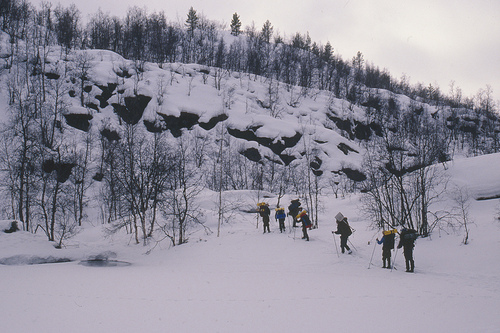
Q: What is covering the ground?
A: Snow.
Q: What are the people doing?
A: Skiing.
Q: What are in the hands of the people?
A: Ski poles.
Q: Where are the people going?
A: Uphill.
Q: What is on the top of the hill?
A: Trees.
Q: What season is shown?
A: Winter.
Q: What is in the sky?
A: Clouds.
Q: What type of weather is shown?
A: Cloudy and cold.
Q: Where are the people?
A: Hiking in the mountains.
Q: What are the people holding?
A: Hiking poles.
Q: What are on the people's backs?
A: Backpacks.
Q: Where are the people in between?
A: Trees.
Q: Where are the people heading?
A: Up the mountain.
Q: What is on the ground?
A: Snow.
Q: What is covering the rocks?
A: Snow.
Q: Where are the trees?
A: On the mountain side.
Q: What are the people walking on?
A: Snow.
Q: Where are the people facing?
A: Away from the camera.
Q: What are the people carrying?
A: Backpacks.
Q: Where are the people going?
A: To the mountain.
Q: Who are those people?
A: Hikers.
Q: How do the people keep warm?
A: Winter clothes.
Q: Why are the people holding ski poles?
A: For balance.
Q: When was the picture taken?
A: During winter.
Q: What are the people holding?
A: Ski poles.